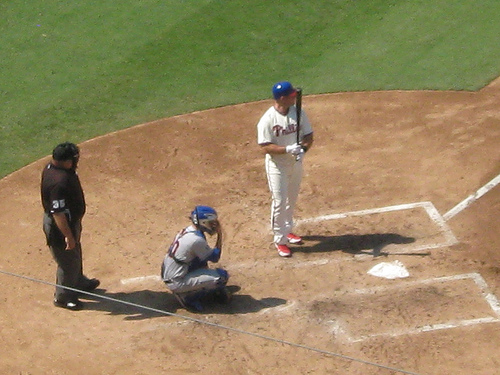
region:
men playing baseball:
[16, 65, 335, 322]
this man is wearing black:
[28, 133, 97, 314]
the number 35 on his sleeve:
[47, 197, 69, 212]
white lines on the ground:
[114, 154, 495, 352]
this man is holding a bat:
[256, 72, 316, 258]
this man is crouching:
[154, 198, 232, 315]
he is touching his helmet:
[185, 207, 228, 265]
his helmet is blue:
[185, 201, 220, 236]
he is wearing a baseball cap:
[268, 80, 303, 100]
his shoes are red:
[270, 227, 303, 258]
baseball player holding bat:
[259, 79, 314, 256]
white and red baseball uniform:
[260, 104, 302, 242]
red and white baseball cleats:
[272, 233, 304, 256]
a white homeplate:
[368, 257, 407, 281]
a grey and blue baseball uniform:
[159, 207, 232, 304]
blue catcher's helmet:
[190, 206, 220, 238]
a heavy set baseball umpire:
[37, 142, 103, 307]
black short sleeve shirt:
[41, 163, 86, 220]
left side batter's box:
[272, 198, 465, 270]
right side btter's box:
[315, 273, 499, 333]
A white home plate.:
[364, 261, 411, 281]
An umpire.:
[38, 139, 109, 306]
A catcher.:
[167, 200, 234, 303]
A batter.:
[259, 79, 314, 262]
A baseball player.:
[255, 77, 312, 261]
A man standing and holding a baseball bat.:
[257, 77, 332, 262]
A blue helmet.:
[264, 79, 301, 100]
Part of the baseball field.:
[2, 1, 499, 373]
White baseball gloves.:
[287, 139, 304, 162]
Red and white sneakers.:
[272, 227, 304, 258]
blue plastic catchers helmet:
[192, 203, 218, 229]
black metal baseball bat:
[295, 86, 301, 156]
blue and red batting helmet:
[271, 79, 301, 96]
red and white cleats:
[273, 230, 303, 259]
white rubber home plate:
[367, 258, 409, 280]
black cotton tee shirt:
[41, 164, 88, 222]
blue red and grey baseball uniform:
[161, 224, 228, 304]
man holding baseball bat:
[258, 80, 315, 259]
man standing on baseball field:
[41, 143, 103, 310]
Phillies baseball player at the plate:
[256, 79, 316, 262]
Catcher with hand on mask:
[159, 200, 232, 319]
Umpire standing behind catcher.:
[40, 139, 101, 317]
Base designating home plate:
[363, 253, 408, 282]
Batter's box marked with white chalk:
[258, 191, 498, 346]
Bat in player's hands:
[291, 83, 306, 166]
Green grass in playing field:
[0, 1, 497, 173]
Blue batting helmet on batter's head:
[269, 82, 295, 103]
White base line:
[436, 154, 495, 224]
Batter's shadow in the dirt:
[288, 226, 433, 266]